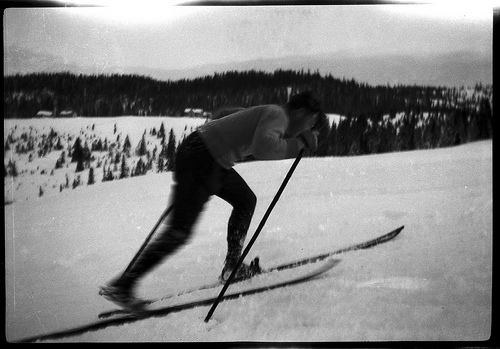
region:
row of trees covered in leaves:
[55, 64, 207, 111]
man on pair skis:
[28, 90, 446, 332]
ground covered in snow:
[330, 162, 482, 222]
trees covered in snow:
[0, 129, 90, 190]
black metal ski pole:
[203, 152, 324, 323]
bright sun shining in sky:
[39, 8, 205, 38]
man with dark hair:
[268, 65, 352, 135]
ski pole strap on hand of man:
[295, 129, 317, 152]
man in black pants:
[107, 128, 296, 345]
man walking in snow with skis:
[94, 65, 432, 334]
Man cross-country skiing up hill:
[23, 93, 423, 334]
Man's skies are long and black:
[60, 224, 436, 347]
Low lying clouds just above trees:
[53, 26, 493, 73]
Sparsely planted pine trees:
[13, 124, 164, 185]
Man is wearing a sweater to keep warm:
[178, 101, 310, 165]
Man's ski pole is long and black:
[205, 126, 313, 334]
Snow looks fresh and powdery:
[62, 166, 467, 335]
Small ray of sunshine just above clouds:
[71, 7, 213, 28]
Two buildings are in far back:
[31, 103, 80, 120]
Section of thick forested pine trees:
[217, 66, 422, 117]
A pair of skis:
[18, 217, 420, 340]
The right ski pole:
[202, 132, 326, 328]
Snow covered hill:
[17, 136, 490, 347]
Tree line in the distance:
[2, 75, 492, 117]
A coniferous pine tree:
[66, 133, 84, 163]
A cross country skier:
[66, 85, 384, 320]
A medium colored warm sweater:
[198, 97, 293, 167]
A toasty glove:
[283, 125, 328, 155]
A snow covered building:
[58, 107, 73, 118]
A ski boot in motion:
[97, 271, 162, 321]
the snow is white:
[398, 167, 475, 237]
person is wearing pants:
[184, 150, 216, 217]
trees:
[27, 127, 113, 179]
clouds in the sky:
[342, 17, 439, 69]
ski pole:
[277, 158, 309, 182]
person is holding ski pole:
[280, 132, 320, 159]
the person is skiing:
[95, 96, 317, 308]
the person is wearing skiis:
[293, 230, 399, 283]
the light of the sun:
[92, 11, 179, 38]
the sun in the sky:
[375, 10, 491, 30]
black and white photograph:
[16, 27, 448, 337]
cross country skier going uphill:
[70, 80, 447, 337]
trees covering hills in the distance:
[30, 41, 450, 120]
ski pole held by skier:
[192, 129, 329, 329]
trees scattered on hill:
[18, 116, 153, 204]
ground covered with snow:
[379, 261, 465, 316]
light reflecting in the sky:
[62, 6, 478, 48]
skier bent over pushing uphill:
[105, 93, 372, 326]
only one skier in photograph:
[27, 55, 469, 340]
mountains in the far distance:
[330, 44, 497, 91]